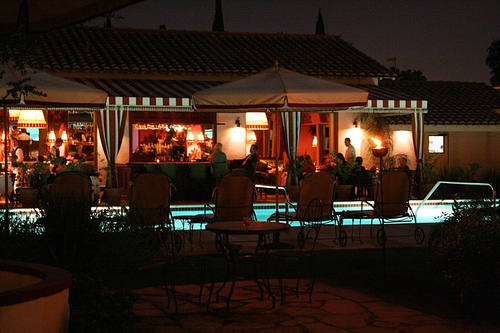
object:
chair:
[124, 169, 182, 228]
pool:
[0, 202, 500, 235]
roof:
[20, 23, 394, 86]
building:
[0, 35, 429, 215]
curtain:
[96, 104, 130, 186]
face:
[344, 140, 350, 147]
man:
[339, 136, 359, 167]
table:
[202, 215, 294, 304]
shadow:
[192, 300, 415, 333]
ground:
[155, 302, 440, 332]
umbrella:
[188, 56, 373, 123]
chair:
[192, 170, 265, 250]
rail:
[412, 178, 498, 220]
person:
[235, 143, 264, 175]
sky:
[104, 0, 500, 81]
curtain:
[408, 110, 431, 161]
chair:
[341, 167, 428, 247]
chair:
[267, 165, 342, 256]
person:
[347, 156, 375, 188]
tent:
[52, 76, 198, 110]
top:
[85, 26, 352, 49]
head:
[246, 143, 261, 154]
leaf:
[442, 213, 448, 216]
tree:
[389, 67, 433, 82]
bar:
[126, 121, 217, 163]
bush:
[434, 193, 499, 284]